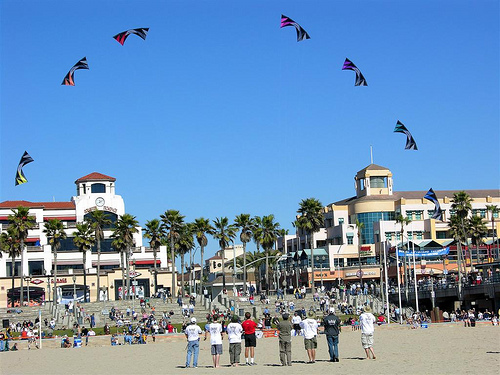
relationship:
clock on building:
[95, 197, 107, 208] [1, 171, 171, 277]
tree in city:
[206, 217, 235, 296] [2, 149, 500, 310]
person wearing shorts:
[298, 310, 319, 364] [303, 336, 318, 351]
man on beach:
[184, 316, 203, 369] [0, 321, 498, 375]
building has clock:
[1, 171, 171, 277] [95, 197, 107, 208]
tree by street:
[206, 217, 235, 296] [2, 282, 375, 310]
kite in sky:
[279, 12, 312, 44] [2, 0, 498, 213]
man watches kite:
[184, 316, 203, 369] [279, 12, 312, 44]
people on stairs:
[110, 294, 174, 336] [2, 291, 396, 327]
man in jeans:
[184, 316, 203, 369] [326, 331, 340, 361]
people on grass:
[110, 294, 174, 336] [8, 315, 362, 340]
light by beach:
[380, 232, 392, 324] [0, 321, 498, 375]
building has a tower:
[1, 171, 171, 277] [73, 171, 127, 225]